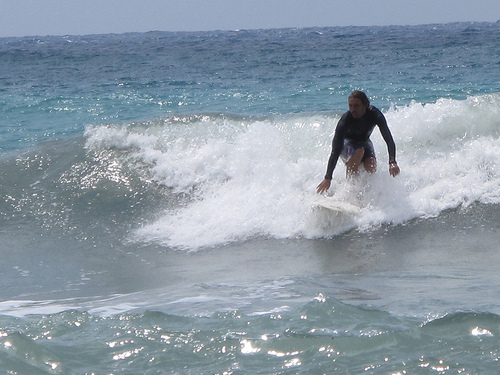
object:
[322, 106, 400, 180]
shirt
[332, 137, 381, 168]
bottoms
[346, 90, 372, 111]
hair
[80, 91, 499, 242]
wave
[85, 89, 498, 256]
cap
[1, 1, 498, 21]
sky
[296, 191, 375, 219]
surfboard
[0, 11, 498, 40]
horizon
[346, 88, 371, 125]
head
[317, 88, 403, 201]
person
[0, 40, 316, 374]
water